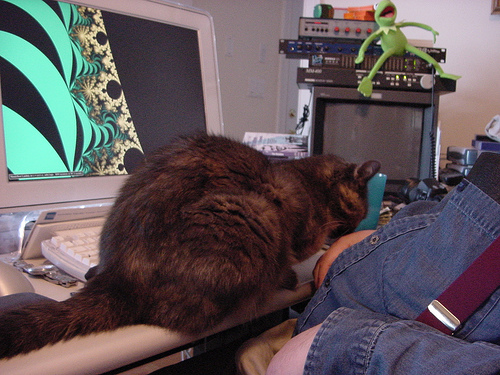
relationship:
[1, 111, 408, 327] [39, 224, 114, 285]
cat on keyboard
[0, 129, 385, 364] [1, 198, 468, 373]
cat lying on desk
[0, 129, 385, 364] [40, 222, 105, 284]
cat lying on computer keyboard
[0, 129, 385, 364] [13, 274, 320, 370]
cat sleeping on counter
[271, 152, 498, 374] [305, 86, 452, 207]
person by tv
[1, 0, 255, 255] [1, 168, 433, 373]
monitor on desk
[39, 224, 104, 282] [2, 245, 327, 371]
keyboard on desk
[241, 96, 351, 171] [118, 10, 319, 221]
book by television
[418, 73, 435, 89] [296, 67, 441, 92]
silver knob on player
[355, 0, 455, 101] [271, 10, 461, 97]
frog in front of electronics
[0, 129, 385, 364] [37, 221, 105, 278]
cat on top of keyboard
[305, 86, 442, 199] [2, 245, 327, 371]
tv on top of desk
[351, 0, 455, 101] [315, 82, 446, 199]
frog on top of tv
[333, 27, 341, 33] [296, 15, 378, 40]
knob on machine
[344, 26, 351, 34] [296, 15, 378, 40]
knob on machine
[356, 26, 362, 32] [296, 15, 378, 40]
knob on machine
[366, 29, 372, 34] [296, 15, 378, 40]
knob on machine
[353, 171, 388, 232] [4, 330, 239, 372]
blue glass on desk